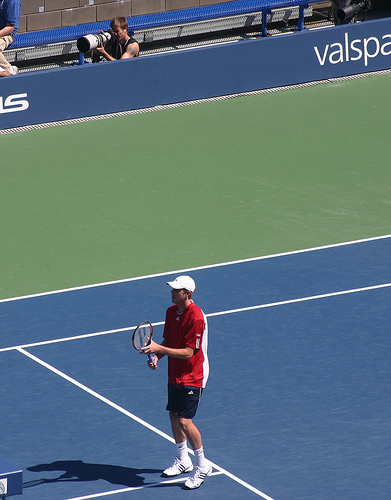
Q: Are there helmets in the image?
A: No, there are no helmets.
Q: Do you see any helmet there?
A: No, there are no helmets.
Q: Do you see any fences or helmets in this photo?
A: No, there are no helmets or fences.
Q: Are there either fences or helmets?
A: No, there are no helmets or fences.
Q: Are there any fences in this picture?
A: No, there are no fences.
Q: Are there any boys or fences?
A: No, there are no fences or boys.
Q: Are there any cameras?
A: Yes, there is a camera.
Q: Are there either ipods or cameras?
A: Yes, there is a camera.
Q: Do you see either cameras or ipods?
A: Yes, there is a camera.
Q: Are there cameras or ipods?
A: Yes, there is a camera.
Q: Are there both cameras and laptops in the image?
A: No, there is a camera but no laptops.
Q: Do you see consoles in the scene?
A: No, there are no consoles.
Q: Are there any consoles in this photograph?
A: No, there are no consoles.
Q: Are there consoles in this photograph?
A: No, there are no consoles.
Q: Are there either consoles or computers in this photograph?
A: No, there are no consoles or computers.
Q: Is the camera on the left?
A: Yes, the camera is on the left of the image.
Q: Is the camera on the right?
A: No, the camera is on the left of the image.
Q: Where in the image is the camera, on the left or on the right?
A: The camera is on the left of the image.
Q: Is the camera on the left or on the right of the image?
A: The camera is on the left of the image.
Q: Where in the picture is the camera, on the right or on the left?
A: The camera is on the left of the image.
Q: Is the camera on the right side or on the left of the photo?
A: The camera is on the left of the image.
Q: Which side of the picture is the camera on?
A: The camera is on the left of the image.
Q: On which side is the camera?
A: The camera is on the left of the image.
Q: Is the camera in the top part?
A: Yes, the camera is in the top of the image.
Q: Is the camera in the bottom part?
A: No, the camera is in the top of the image.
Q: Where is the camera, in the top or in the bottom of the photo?
A: The camera is in the top of the image.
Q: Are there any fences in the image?
A: No, there are no fences.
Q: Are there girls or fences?
A: No, there are no fences or girls.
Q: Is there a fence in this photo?
A: No, there are no fences.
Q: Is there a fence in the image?
A: No, there are no fences.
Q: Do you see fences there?
A: No, there are no fences.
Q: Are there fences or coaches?
A: No, there are no fences or coaches.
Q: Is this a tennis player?
A: Yes, this is a tennis player.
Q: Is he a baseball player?
A: No, this is a tennis player.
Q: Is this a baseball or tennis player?
A: This is a tennis player.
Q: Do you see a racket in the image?
A: Yes, there is a racket.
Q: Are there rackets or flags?
A: Yes, there is a racket.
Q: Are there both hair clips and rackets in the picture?
A: No, there is a racket but no hair clips.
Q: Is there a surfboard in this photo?
A: No, there are no surfboards.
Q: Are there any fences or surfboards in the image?
A: No, there are no surfboards or fences.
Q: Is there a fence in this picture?
A: No, there are no fences.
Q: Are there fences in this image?
A: No, there are no fences.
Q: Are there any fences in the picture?
A: No, there are no fences.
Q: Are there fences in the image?
A: No, there are no fences.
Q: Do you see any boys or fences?
A: No, there are no fences or boys.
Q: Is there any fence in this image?
A: No, there are no fences.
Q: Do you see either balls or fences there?
A: No, there are no fences or balls.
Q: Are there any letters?
A: Yes, there are letters.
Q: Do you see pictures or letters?
A: Yes, there are letters.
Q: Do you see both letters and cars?
A: No, there are letters but no cars.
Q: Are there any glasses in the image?
A: No, there are no glasses.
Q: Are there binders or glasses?
A: No, there are no glasses or binders.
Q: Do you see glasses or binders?
A: No, there are no glasses or binders.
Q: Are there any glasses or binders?
A: No, there are no glasses or binders.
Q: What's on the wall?
A: The letters are on the wall.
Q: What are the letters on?
A: The letters are on the wall.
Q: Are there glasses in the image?
A: No, there are no glasses.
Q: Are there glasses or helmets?
A: No, there are no glasses or helmets.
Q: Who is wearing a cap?
A: The man is wearing a cap.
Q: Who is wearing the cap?
A: The man is wearing a cap.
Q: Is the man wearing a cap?
A: Yes, the man is wearing a cap.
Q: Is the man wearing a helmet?
A: No, the man is wearing a cap.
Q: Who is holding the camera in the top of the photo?
A: The man is holding the camera.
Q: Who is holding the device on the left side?
A: The man is holding the camera.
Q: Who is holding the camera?
A: The man is holding the camera.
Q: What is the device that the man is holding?
A: The device is a camera.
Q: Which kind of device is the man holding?
A: The man is holding the camera.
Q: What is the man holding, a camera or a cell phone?
A: The man is holding a camera.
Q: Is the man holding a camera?
A: Yes, the man is holding a camera.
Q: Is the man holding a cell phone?
A: No, the man is holding a camera.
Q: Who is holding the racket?
A: The man is holding the racket.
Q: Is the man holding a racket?
A: Yes, the man is holding a racket.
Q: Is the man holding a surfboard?
A: No, the man is holding a racket.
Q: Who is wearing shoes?
A: The man is wearing shoes.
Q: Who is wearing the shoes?
A: The man is wearing shoes.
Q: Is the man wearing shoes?
A: Yes, the man is wearing shoes.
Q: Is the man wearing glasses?
A: No, the man is wearing shoes.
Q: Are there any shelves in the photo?
A: No, there are no shelves.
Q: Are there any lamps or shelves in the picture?
A: No, there are no shelves or lamps.